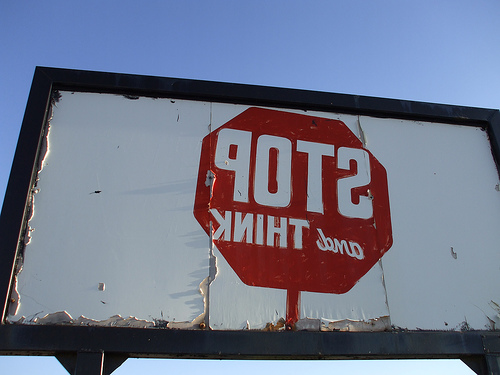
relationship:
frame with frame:
[0, 59, 499, 375] [3, 64, 499, 374]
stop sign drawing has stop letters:
[192, 109, 394, 331] [214, 129, 375, 220]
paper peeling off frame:
[6, 86, 499, 342] [0, 59, 499, 375]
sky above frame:
[2, 4, 495, 374] [0, 59, 499, 375]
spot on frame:
[265, 315, 286, 330] [0, 59, 499, 375]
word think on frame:
[208, 207, 309, 251] [0, 59, 499, 375]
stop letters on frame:
[214, 129, 375, 220] [0, 59, 499, 375]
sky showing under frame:
[2, 4, 495, 374] [0, 59, 499, 375]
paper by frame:
[6, 86, 499, 342] [3, 64, 499, 374]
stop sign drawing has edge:
[192, 109, 394, 331] [338, 116, 383, 171]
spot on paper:
[265, 315, 286, 330] [6, 86, 499, 342]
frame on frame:
[3, 64, 499, 374] [0, 59, 499, 375]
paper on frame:
[6, 86, 499, 342] [0, 59, 499, 375]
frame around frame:
[3, 64, 499, 374] [0, 59, 499, 375]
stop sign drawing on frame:
[192, 109, 394, 331] [0, 59, 499, 375]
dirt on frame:
[93, 187, 104, 197] [0, 59, 499, 375]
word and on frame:
[315, 226, 365, 261] [0, 59, 499, 375]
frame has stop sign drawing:
[0, 59, 499, 375] [192, 109, 394, 331]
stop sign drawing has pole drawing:
[192, 109, 394, 331] [286, 288, 303, 329]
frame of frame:
[3, 64, 499, 374] [0, 59, 499, 375]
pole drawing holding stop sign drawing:
[286, 288, 303, 329] [192, 109, 394, 331]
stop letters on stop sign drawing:
[214, 129, 375, 220] [192, 109, 394, 331]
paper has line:
[6, 86, 499, 342] [203, 103, 220, 329]